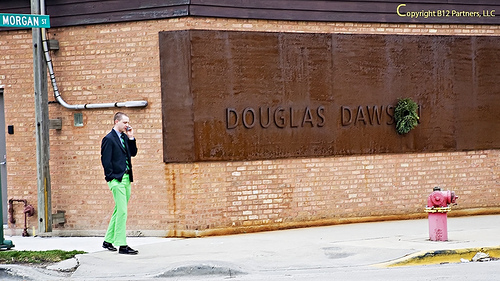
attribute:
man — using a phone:
[101, 100, 146, 262]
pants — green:
[102, 171, 130, 245]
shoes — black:
[98, 238, 143, 254]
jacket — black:
[100, 127, 138, 184]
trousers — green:
[99, 168, 145, 255]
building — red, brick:
[170, 28, 456, 210]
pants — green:
[106, 174, 130, 247]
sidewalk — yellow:
[404, 247, 498, 262]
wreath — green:
[387, 98, 430, 145]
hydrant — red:
[422, 183, 462, 244]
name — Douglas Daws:
[224, 104, 398, 126]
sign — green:
[0, 12, 50, 29]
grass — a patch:
[6, 242, 44, 260]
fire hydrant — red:
[406, 178, 470, 262]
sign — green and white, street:
[2, 3, 56, 38]